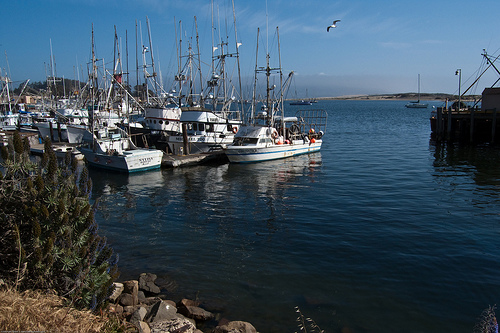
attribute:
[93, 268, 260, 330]
pile — rock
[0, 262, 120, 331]
grass — brown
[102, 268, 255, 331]
rocks — brown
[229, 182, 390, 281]
water — calm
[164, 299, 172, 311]
line — tiny, white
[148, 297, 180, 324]
rock — small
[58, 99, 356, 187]
boats — white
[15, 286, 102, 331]
grass — dry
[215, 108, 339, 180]
boats — white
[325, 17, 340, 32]
bird — flying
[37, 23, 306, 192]
boats — white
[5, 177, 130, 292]
bushes — evergreen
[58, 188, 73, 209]
flowers — dark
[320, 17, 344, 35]
seagull — white, flying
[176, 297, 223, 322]
gray rock — grey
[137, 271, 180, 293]
gray rock — grey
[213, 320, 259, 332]
gray rock — grey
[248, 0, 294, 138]
mast — tall 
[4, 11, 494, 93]
sky — blue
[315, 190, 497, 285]
water — calm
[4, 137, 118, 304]
vegetation — rough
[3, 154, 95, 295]
shrub — evergreen